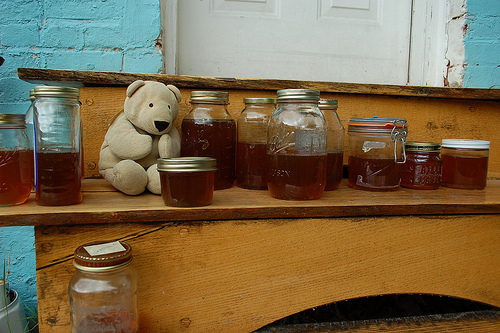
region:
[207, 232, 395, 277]
The wood is brown.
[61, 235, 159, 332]
The jars is made of glass.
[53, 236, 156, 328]
The jar is clear.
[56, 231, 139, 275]
A lid is on the jar.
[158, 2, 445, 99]
The door is white.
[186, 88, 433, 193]
Something is in the jars.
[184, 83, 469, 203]
The jars are half full.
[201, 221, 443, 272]
The shelf is made of wood.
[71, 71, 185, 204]
A bear.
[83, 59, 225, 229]
The bear is a toy.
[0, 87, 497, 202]
ten jars of honey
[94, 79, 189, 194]
one creamy beige stuffed bear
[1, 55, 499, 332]
wooden steps used as shelves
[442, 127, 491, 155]
a white lid on a short jar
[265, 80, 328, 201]
a Ball mason jar half filled with honey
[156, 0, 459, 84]
a white panal door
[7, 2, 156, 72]
turquoise painted brick wall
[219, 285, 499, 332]
arched bottom of step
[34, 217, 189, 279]
a cracked piece of wood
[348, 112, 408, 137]
red rubber ring to form seal on jar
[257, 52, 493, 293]
the jars are visible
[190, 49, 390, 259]
the jars are visible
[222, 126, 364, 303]
the jars are visible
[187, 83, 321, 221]
the jars are visible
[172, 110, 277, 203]
the jars are visible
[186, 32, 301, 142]
the jars are visible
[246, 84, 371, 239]
the jars are visible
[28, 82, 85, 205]
a large jar of honey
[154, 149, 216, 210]
a large jar of honey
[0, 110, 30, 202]
a large jar of honey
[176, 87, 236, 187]
a large jar of honey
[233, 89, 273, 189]
a large jar of honey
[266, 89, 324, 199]
a large jar of honey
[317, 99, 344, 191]
a large jar of honey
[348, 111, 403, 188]
a large jar of honey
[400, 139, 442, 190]
a large jar of honey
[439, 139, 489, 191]
a large jar of honey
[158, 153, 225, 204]
little honey jar on top of a shelf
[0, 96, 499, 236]
brown shelf with lots of honey in jars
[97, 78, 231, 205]
old teddy bear sitting on top of brown shelf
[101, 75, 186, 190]
stuffed tan teddy bear with a black nose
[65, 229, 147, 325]
glass jar with a brown lid and white note on top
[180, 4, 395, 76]
white door above step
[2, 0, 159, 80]
blue painted bricks building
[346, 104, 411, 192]
clear glass jar with a stopper to push up and down to seal jar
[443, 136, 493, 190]
clear jar with a white lid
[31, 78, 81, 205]
tall glass jar with a copper lid